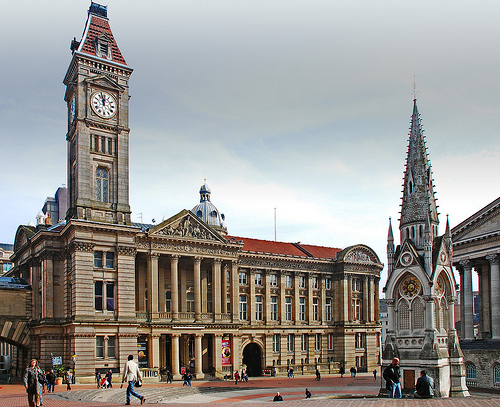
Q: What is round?
A: Clocks.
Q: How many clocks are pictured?
A: Three.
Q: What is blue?
A: Sky.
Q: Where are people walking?
A: In a square.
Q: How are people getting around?
A: Walking.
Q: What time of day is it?
A: Noon.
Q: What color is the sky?
A: Gray and blue.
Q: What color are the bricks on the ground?
A: Red, gray and white.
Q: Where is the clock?
A: On top of the tall tower.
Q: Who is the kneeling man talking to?
A: A man on the ground.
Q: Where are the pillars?
A: In front of the big building.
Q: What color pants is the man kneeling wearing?
A: Blue.